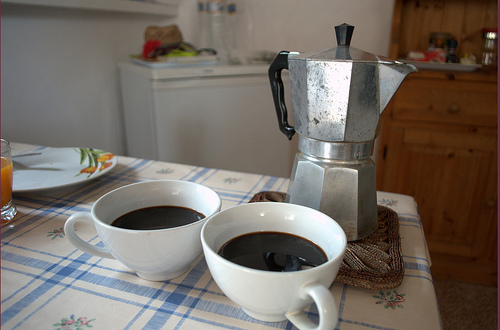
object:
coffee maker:
[266, 24, 417, 241]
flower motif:
[74, 164, 97, 179]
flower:
[97, 159, 114, 170]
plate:
[10, 146, 119, 192]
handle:
[283, 283, 339, 329]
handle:
[267, 51, 297, 141]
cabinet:
[390, 131, 500, 261]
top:
[332, 22, 356, 46]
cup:
[199, 201, 348, 330]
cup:
[63, 178, 223, 282]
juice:
[0, 157, 12, 205]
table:
[0, 142, 441, 330]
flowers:
[97, 152, 116, 162]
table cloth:
[0, 139, 445, 329]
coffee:
[110, 206, 205, 232]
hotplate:
[244, 190, 406, 292]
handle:
[63, 210, 113, 260]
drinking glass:
[0, 140, 19, 228]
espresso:
[217, 230, 329, 275]